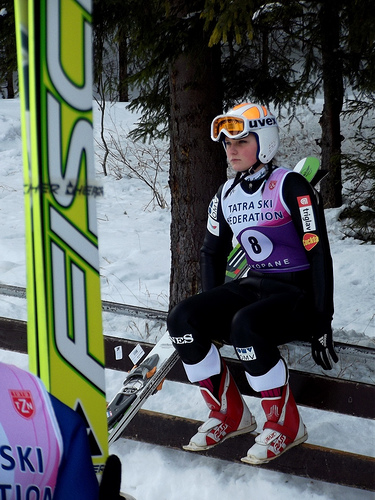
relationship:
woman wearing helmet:
[164, 101, 338, 467] [210, 102, 283, 166]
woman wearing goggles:
[164, 101, 338, 467] [209, 112, 278, 144]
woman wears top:
[164, 101, 338, 467] [202, 165, 338, 325]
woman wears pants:
[164, 101, 338, 467] [167, 270, 327, 374]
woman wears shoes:
[164, 101, 338, 467] [242, 360, 310, 467]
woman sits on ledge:
[164, 101, 338, 467] [2, 284, 375, 492]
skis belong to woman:
[107, 155, 328, 447] [164, 101, 338, 467]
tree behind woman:
[95, 1, 292, 335] [164, 101, 338, 467]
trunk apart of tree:
[160, 10, 235, 321] [95, 1, 292, 335]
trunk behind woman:
[160, 10, 235, 321] [164, 101, 338, 467]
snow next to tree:
[0, 62, 373, 363] [95, 1, 292, 335]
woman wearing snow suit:
[164, 101, 338, 467] [163, 165, 336, 386]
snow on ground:
[0, 62, 373, 363] [0, 93, 373, 351]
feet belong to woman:
[184, 344, 309, 468] [164, 101, 338, 467]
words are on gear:
[47, 2, 107, 402] [14, 0, 112, 492]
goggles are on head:
[209, 112, 278, 144] [211, 105, 279, 172]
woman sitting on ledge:
[164, 101, 338, 467] [2, 284, 375, 492]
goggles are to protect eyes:
[209, 112, 278, 144] [222, 140, 254, 145]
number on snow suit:
[247, 237, 263, 253] [163, 165, 336, 386]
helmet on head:
[210, 102, 283, 166] [211, 105, 279, 172]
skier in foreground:
[1, 357, 126, 499] [0, 286, 375, 499]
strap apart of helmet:
[223, 161, 261, 200] [210, 102, 283, 166]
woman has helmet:
[164, 101, 338, 467] [210, 102, 283, 166]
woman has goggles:
[164, 101, 338, 467] [209, 112, 278, 144]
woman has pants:
[164, 101, 338, 467] [167, 270, 327, 374]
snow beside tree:
[0, 62, 373, 363] [95, 1, 292, 335]